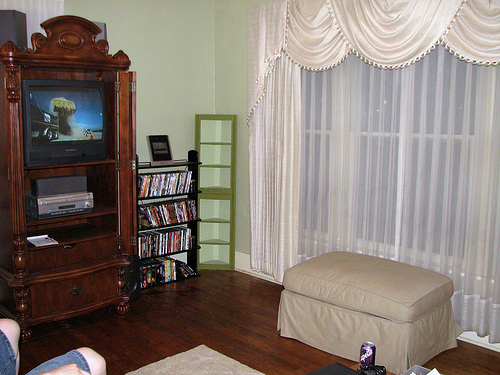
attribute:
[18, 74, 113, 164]
television — black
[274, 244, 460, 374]
ottoman — beige, ivory colored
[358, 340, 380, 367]
soda — purple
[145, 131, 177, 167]
picture — framed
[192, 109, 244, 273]
rack — green, empty, for plants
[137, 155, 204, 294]
dvd rack — for movies, black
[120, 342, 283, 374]
rug — beige, white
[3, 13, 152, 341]
entertainment center — wooden, tall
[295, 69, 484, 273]
curtains — white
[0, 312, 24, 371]
leg — from a person, here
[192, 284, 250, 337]
floor — wooden, shiny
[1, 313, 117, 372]
knees — here